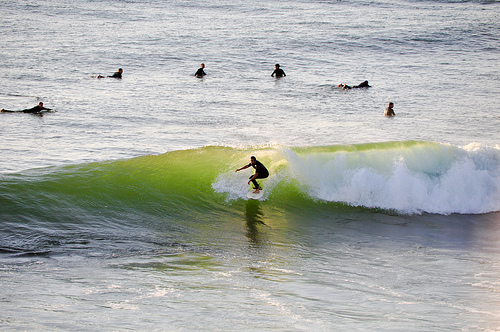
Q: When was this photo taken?
A: Photo taken during the day.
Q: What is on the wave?
A: Whitecaps.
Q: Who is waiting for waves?
A: Six surfers.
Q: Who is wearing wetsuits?
A: Seven people.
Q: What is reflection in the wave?
A: Light.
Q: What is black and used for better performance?
A: The wet suits.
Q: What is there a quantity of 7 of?
A: Surfers in the water.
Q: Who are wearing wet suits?
A: Surfers.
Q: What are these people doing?
A: Watching the other surfer.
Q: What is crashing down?
A: The wave.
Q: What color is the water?
A: Blue, green, and white.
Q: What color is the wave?
A: Green.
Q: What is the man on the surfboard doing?
A: Surfing.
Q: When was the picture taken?
A: Daytime.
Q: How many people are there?
A: Seven.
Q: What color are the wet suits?
A: Black.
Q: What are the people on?
A: Surfboards.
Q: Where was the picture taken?
A: At the ocean.